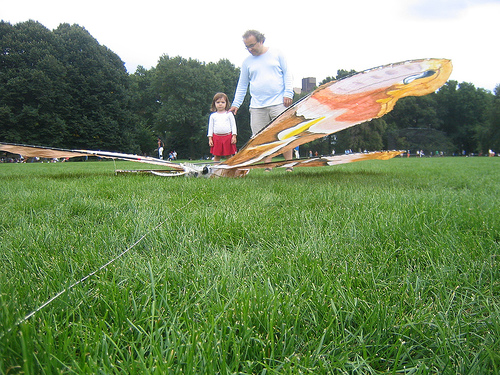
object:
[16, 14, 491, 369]
park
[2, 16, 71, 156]
tree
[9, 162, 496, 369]
grass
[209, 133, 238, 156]
red skirt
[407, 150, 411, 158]
people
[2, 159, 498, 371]
field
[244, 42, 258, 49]
glasses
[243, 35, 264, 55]
face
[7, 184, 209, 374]
string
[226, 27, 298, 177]
man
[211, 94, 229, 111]
hair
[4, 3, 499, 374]
photo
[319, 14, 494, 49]
sky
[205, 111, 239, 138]
shirt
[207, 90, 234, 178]
girl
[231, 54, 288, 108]
shirt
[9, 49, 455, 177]
kite